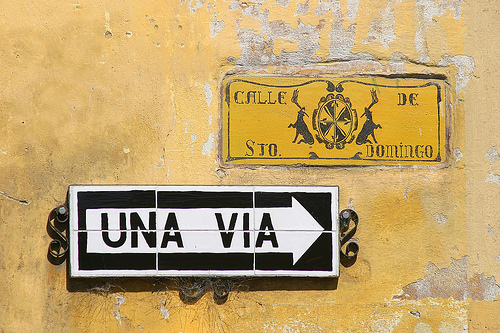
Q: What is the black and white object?
A: Sign.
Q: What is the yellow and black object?
A: Sign.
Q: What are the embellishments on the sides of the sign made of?
A: Metal.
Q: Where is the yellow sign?
A: In the wall.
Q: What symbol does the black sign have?
A: Arrow.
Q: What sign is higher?
A: Yellow.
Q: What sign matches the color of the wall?
A: Yellow.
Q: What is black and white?
A: Sign.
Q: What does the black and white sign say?
A: UNA VIA.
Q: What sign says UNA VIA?
A: Black and white.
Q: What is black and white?
A: The arrow.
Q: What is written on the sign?
A: Una via.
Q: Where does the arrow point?
A: To the right.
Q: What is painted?
A: The wall.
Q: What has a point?
A: The arrow.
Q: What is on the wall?
A: Two signs.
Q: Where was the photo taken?
A: In front of a wall.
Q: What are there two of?
A: Signs.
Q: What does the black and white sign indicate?
A: Directions.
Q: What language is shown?
A: Spanish.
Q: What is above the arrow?
A: A yellow sign.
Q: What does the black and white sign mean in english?
A: One way.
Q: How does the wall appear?
A: Distressed.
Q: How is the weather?
A: Sunny.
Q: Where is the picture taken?
A: A wall.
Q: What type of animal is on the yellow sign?
A: Deer.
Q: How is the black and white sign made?
A: Of tile.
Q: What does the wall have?
A: Chipped paint and plaster.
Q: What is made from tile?
A: The sign.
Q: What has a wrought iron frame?
A: The sign.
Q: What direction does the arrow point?
A: Right.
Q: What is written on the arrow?
A: UNA VIA.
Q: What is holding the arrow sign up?
A: Nails.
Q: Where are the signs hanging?
A: Wall of the building.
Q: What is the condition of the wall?
A: Dirty.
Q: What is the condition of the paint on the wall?
A: Chipped.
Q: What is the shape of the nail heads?
A: Round.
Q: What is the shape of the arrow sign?
A: Rectangle.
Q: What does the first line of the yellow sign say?
A: Calle DE.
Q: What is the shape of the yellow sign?
A: Rectangle.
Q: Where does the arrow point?
A: Right.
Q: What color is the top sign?
A: Yellow.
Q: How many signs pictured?
A: 2.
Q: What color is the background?
A: Yellow.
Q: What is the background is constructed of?
A: Cement.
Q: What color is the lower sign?
A: Black/white.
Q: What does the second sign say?
A: UNA VIA.